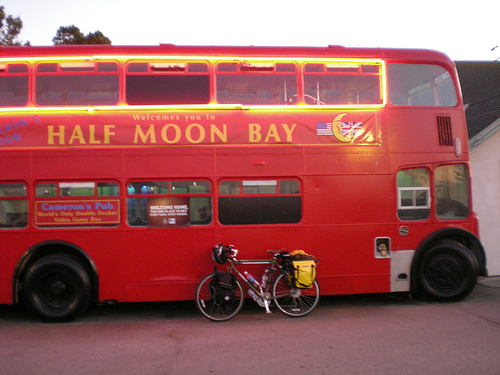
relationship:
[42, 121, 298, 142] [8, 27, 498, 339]
words on bus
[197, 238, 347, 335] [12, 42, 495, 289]
bike by bus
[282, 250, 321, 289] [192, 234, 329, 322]
bag on bike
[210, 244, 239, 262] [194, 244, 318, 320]
helmet on bike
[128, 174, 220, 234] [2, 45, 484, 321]
window on bus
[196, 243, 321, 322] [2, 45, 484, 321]
bike against bus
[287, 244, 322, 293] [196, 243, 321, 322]
bag on bike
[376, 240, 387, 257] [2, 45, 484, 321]
spot on bus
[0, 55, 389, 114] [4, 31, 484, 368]
light on bus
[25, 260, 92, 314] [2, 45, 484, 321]
tire on bus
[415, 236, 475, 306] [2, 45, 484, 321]
tire on bus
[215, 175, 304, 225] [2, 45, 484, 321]
window on bus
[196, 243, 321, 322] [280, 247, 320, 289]
bike has bag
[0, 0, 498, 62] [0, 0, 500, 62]
clouds in sky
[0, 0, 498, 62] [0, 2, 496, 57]
clouds in sky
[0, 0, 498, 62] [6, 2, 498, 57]
clouds in sky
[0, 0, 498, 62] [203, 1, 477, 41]
clouds in sky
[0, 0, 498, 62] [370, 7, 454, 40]
clouds in sky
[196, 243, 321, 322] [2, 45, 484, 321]
bike on bus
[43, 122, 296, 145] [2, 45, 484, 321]
writing on bus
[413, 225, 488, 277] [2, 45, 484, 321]
fender of bus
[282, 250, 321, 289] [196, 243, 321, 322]
bag on bike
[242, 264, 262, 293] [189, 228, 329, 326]
water bottle on bike